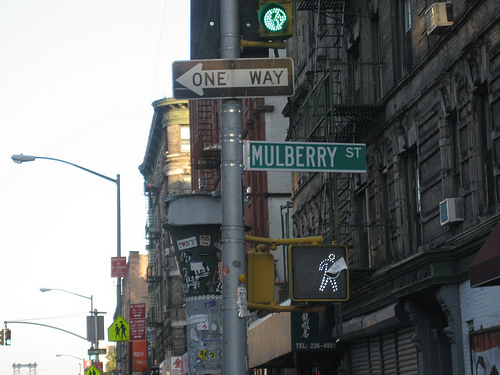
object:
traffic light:
[257, 7, 293, 34]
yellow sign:
[240, 5, 295, 53]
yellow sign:
[245, 232, 352, 313]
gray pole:
[218, 0, 251, 372]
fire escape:
[312, 30, 385, 257]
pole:
[88, 295, 95, 313]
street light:
[9, 149, 37, 164]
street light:
[39, 285, 53, 292]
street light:
[53, 351, 62, 358]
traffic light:
[0, 327, 7, 344]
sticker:
[173, 230, 198, 253]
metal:
[166, 229, 221, 297]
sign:
[106, 317, 131, 341]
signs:
[242, 134, 369, 176]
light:
[14, 159, 22, 165]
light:
[37, 285, 49, 294]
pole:
[87, 296, 99, 371]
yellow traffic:
[242, 231, 352, 312]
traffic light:
[316, 253, 350, 296]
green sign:
[247, 141, 368, 170]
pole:
[117, 176, 121, 373]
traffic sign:
[166, 54, 294, 96]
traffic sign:
[290, 235, 350, 304]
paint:
[457, 277, 499, 375]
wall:
[455, 268, 499, 374]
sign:
[110, 256, 125, 276]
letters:
[250, 143, 367, 169]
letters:
[188, 69, 284, 86]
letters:
[131, 340, 149, 371]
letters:
[111, 256, 126, 277]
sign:
[128, 302, 146, 339]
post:
[162, 217, 223, 297]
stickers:
[178, 247, 196, 262]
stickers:
[202, 299, 219, 310]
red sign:
[108, 253, 130, 283]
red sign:
[124, 300, 149, 342]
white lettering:
[111, 256, 128, 277]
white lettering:
[245, 141, 367, 172]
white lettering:
[128, 304, 148, 342]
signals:
[313, 250, 341, 296]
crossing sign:
[317, 252, 341, 294]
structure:
[164, 188, 223, 373]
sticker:
[198, 233, 210, 245]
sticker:
[198, 249, 213, 259]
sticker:
[181, 249, 193, 263]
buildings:
[116, 0, 498, 373]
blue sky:
[1, 0, 173, 89]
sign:
[240, 134, 377, 182]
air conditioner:
[433, 192, 471, 227]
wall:
[388, 57, 499, 195]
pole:
[210, 1, 252, 374]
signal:
[5, 327, 12, 345]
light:
[6, 338, 12, 343]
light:
[263, 5, 287, 33]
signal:
[257, 7, 290, 32]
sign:
[171, 59, 296, 99]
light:
[316, 253, 343, 293]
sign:
[220, 0, 247, 373]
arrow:
[174, 62, 292, 97]